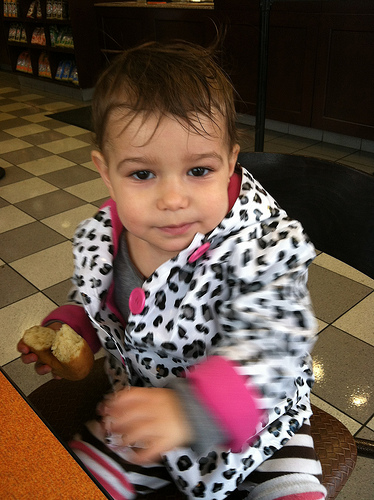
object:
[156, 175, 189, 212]
nose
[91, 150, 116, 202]
ear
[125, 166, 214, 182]
eyes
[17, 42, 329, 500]
baby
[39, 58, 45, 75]
snack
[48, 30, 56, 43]
snack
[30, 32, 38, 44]
snack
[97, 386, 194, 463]
hand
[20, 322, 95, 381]
bagel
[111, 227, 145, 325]
shirt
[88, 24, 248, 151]
brown hair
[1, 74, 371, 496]
floor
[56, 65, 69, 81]
chips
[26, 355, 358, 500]
chair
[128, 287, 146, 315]
button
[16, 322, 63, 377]
hand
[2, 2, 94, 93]
display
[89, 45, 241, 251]
head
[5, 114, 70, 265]
ground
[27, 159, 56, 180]
tile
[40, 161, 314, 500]
jacket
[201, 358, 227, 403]
trim